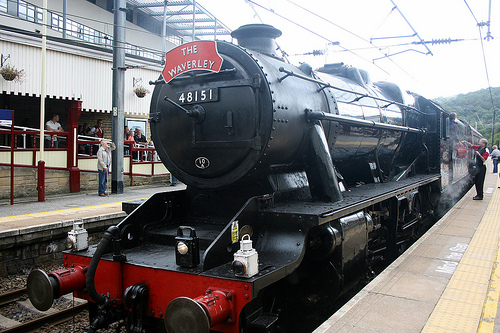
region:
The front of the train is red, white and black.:
[147, 38, 273, 181]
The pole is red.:
[36, 160, 44, 198]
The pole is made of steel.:
[33, 157, 50, 199]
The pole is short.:
[33, 158, 50, 203]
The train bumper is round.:
[23, 263, 53, 313]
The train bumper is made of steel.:
[21, 267, 56, 312]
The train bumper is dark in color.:
[23, 269, 56, 308]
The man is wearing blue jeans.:
[94, 138, 111, 195]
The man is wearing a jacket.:
[93, 137, 113, 194]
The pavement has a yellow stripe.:
[453, 276, 498, 328]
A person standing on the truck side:
[98, 138, 122, 208]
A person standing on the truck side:
[467, 117, 485, 217]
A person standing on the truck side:
[489, 136, 499, 173]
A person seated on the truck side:
[39, 110, 62, 155]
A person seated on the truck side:
[89, 112, 106, 142]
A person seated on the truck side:
[135, 127, 152, 152]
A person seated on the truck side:
[94, 117, 106, 137]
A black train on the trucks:
[136, 41, 395, 326]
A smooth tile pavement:
[384, 280, 491, 330]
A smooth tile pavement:
[454, 205, 489, 288]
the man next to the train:
[463, 136, 490, 202]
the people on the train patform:
[464, 134, 498, 199]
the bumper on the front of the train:
[24, 258, 92, 314]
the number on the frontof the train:
[178, 87, 215, 107]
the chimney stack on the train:
[230, 19, 281, 56]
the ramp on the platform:
[0, 131, 152, 199]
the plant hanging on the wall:
[0, 53, 25, 83]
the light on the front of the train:
[164, 220, 203, 270]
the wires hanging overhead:
[296, 0, 482, 72]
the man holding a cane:
[93, 136, 120, 199]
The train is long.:
[24, 15, 495, 330]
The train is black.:
[23, 15, 499, 331]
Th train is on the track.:
[16, 9, 498, 331]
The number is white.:
[176, 90, 186, 103]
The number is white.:
[184, 87, 193, 103]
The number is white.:
[191, 88, 199, 103]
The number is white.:
[198, 85, 207, 100]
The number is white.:
[206, 84, 216, 103]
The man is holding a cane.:
[90, 130, 121, 201]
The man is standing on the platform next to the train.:
[453, 122, 493, 209]